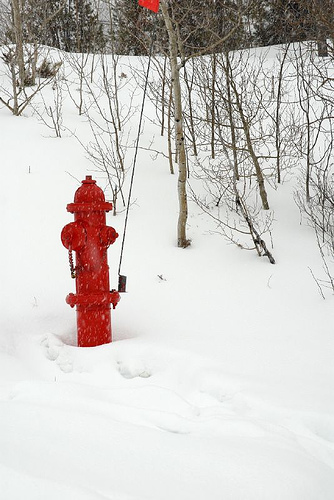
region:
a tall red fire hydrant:
[61, 176, 123, 346]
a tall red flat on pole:
[110, 0, 161, 283]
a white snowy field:
[1, 45, 333, 498]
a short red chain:
[64, 248, 81, 278]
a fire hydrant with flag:
[59, 0, 162, 348]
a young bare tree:
[162, 0, 245, 246]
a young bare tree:
[196, 0, 270, 207]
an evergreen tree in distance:
[64, 0, 107, 54]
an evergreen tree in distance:
[107, 0, 149, 54]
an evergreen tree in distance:
[163, 0, 215, 52]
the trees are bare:
[148, 50, 327, 197]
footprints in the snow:
[121, 357, 326, 474]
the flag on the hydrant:
[117, 1, 163, 294]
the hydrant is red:
[58, 160, 119, 345]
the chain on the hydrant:
[62, 238, 82, 277]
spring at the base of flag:
[104, 270, 128, 295]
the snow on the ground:
[177, 303, 281, 413]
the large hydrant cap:
[52, 223, 98, 258]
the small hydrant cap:
[95, 221, 122, 254]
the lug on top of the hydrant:
[80, 172, 98, 180]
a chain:
[63, 249, 78, 272]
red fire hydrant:
[65, 177, 114, 347]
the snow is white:
[155, 318, 296, 439]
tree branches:
[205, 202, 238, 244]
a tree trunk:
[161, 74, 197, 244]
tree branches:
[200, 55, 283, 175]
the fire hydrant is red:
[61, 191, 136, 347]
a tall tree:
[159, 1, 200, 242]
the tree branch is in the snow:
[224, 213, 280, 264]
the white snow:
[172, 337, 318, 468]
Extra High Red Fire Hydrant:
[59, 171, 121, 353]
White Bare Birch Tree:
[141, 1, 228, 241]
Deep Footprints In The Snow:
[42, 337, 332, 468]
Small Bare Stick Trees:
[171, 60, 332, 277]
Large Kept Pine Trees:
[2, 2, 331, 54]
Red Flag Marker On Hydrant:
[120, 0, 150, 293]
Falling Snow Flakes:
[63, 174, 121, 349]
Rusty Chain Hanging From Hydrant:
[57, 239, 85, 281]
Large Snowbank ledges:
[2, 40, 332, 70]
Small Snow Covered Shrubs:
[2, 47, 64, 92]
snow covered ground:
[0, 37, 331, 487]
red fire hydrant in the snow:
[57, 171, 114, 341]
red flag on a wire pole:
[114, 0, 154, 289]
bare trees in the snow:
[0, 0, 331, 293]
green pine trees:
[1, 0, 328, 51]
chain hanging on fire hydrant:
[58, 173, 113, 342]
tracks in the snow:
[40, 336, 154, 381]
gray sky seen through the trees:
[3, 1, 283, 51]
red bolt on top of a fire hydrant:
[60, 174, 121, 346]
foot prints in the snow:
[193, 374, 333, 444]